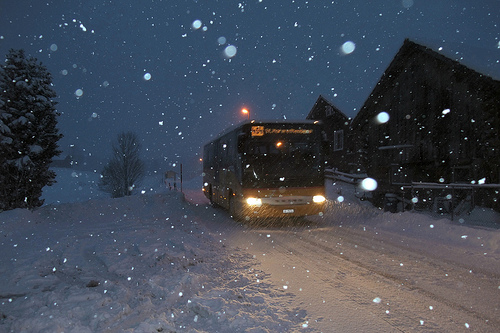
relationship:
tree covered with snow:
[2, 45, 63, 212] [7, 102, 44, 165]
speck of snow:
[351, 172, 381, 195] [352, 97, 404, 154]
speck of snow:
[426, 302, 433, 309] [372, 108, 393, 128]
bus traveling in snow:
[200, 119, 329, 226] [256, 227, 398, 282]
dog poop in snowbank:
[85, 270, 108, 296] [34, 202, 257, 326]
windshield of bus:
[236, 130, 324, 190] [200, 119, 329, 226]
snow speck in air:
[268, 55, 278, 64] [2, 7, 498, 183]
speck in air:
[371, 295, 382, 306] [2, 7, 498, 183]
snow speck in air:
[176, 292, 183, 298] [2, 7, 498, 183]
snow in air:
[340, 38, 358, 56] [2, 7, 498, 183]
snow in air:
[272, 59, 278, 65] [2, 7, 498, 183]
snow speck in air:
[287, 17, 299, 28] [2, 7, 498, 183]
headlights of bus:
[223, 165, 352, 227] [151, 62, 361, 254]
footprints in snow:
[158, 227, 292, 324] [3, 200, 496, 324]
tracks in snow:
[291, 213, 492, 327] [6, 168, 498, 330]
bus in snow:
[200, 119, 329, 226] [393, 230, 497, 279]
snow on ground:
[6, 168, 498, 330] [0, 164, 496, 330]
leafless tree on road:
[110, 133, 145, 201] [306, 227, 451, 329]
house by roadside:
[307, 36, 499, 195] [156, 177, 494, 320]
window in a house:
[326, 121, 353, 163] [313, 27, 484, 227]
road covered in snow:
[264, 216, 430, 331] [343, 237, 471, 320]